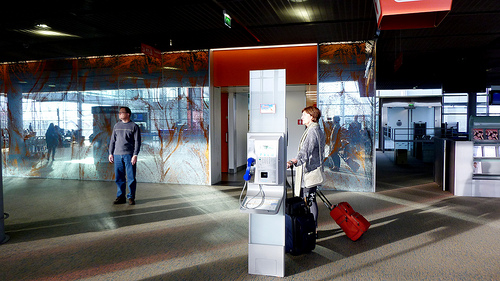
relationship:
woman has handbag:
[289, 101, 328, 257] [292, 127, 325, 190]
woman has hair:
[289, 101, 328, 257] [300, 103, 321, 124]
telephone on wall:
[246, 135, 287, 193] [247, 68, 292, 279]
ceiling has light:
[1, 1, 499, 100] [14, 19, 85, 47]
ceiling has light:
[1, 1, 499, 100] [264, 2, 343, 29]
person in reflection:
[289, 101, 328, 257] [319, 104, 375, 190]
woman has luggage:
[289, 101, 328, 257] [323, 201, 373, 243]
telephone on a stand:
[246, 135, 287, 193] [247, 68, 292, 279]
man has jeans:
[111, 105, 143, 206] [110, 154, 136, 202]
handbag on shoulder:
[295, 130, 326, 188] [303, 130, 322, 149]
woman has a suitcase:
[289, 101, 328, 257] [327, 201, 373, 243]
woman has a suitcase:
[289, 101, 328, 257] [284, 194, 319, 259]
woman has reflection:
[289, 101, 328, 257] [319, 104, 375, 190]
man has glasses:
[111, 105, 143, 206] [118, 110, 131, 116]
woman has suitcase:
[289, 101, 328, 257] [327, 201, 373, 243]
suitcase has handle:
[284, 194, 319, 259] [284, 160, 300, 199]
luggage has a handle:
[323, 201, 373, 243] [314, 183, 337, 211]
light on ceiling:
[14, 19, 85, 47] [1, 1, 499, 100]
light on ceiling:
[264, 2, 343, 29] [1, 1, 499, 100]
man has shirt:
[111, 105, 143, 206] [109, 120, 142, 160]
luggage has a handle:
[327, 201, 373, 243] [314, 183, 337, 211]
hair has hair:
[117, 106, 132, 124] [300, 103, 321, 124]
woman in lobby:
[289, 101, 328, 257] [0, 46, 492, 273]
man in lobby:
[111, 105, 143, 206] [0, 46, 492, 273]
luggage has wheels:
[323, 201, 373, 243] [358, 235, 368, 242]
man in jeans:
[111, 105, 143, 206] [110, 154, 136, 202]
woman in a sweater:
[289, 101, 328, 257] [294, 125, 325, 181]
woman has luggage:
[289, 101, 328, 257] [327, 201, 373, 243]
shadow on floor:
[145, 196, 214, 236] [7, 147, 497, 278]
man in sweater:
[111, 105, 143, 206] [109, 120, 142, 160]